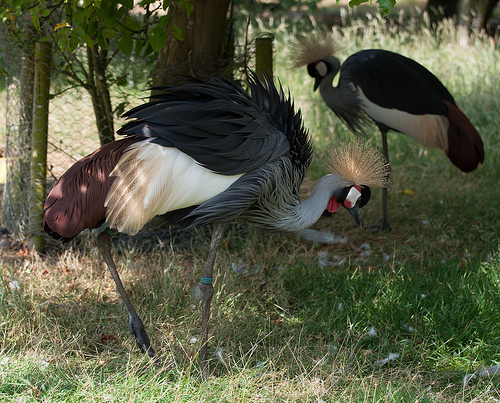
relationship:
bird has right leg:
[41, 59, 394, 376] [192, 208, 225, 382]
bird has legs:
[294, 32, 489, 235] [369, 124, 406, 233]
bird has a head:
[41, 59, 394, 376] [319, 136, 393, 232]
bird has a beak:
[41, 59, 394, 376] [348, 203, 365, 233]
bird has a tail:
[41, 59, 394, 376] [40, 131, 153, 241]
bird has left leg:
[41, 59, 394, 376] [90, 214, 165, 367]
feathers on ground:
[176, 199, 497, 396] [0, 121, 498, 402]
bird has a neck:
[41, 59, 394, 376] [268, 164, 337, 229]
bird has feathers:
[41, 59, 394, 376] [33, 59, 393, 247]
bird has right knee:
[41, 59, 394, 376] [194, 276, 215, 300]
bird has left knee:
[41, 59, 394, 376] [89, 231, 117, 253]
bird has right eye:
[41, 59, 394, 376] [356, 197, 367, 211]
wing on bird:
[339, 46, 454, 152] [294, 32, 489, 235]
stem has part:
[28, 40, 57, 253] [30, 33, 58, 93]